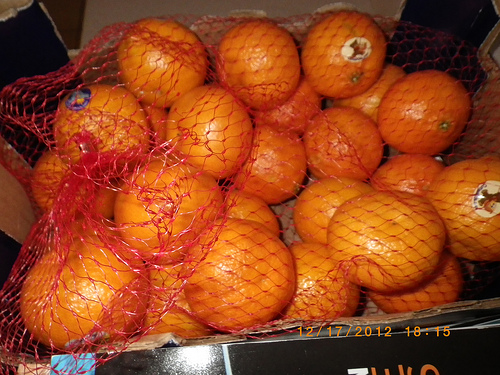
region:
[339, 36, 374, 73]
sticker on an orange fruit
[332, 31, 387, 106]
sticker on an orange fruit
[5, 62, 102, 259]
portion of red mesh bag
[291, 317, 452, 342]
date and time picture was taken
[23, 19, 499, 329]
large bag of oranges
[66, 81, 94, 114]
sticker on an orange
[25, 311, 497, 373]
black printed box oranges are in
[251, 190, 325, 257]
the bottom of the box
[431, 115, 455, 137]
the end of the orange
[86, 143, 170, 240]
a hole torn in the bag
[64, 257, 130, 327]
light reflects off orange rind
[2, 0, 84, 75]
torn edges of the box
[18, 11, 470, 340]
Red netting over oranges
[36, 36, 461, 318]
Pile of oranges in box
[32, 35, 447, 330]
The fruit is round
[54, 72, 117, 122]
Blue sticker on orange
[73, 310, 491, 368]
Side of box is black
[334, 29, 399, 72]
White and brown sticker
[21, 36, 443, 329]
Bag of oranges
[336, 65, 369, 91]
Orange has a green stem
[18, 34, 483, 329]
Oranges piled on top of each other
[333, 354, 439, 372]
Orange letters on side of box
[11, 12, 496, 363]
bags of oranges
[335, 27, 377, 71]
sticker on orange is white and brown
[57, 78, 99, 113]
sticker is blue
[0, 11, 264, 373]
bag of oranges is red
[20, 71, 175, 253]
bag with oranges is a net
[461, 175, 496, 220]
sticker over orange is yellow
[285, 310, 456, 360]
picture was taken on 2012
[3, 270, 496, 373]
oranges are on a black surface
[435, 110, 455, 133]
center of orange has a brown spot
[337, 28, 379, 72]
sticker has a brown design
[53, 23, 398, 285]
oranges in bag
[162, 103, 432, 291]
fruits are orange and round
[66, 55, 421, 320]
bag is red and mesh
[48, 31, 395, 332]
red bag in brown cardboard box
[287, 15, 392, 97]
oranges are small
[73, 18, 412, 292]
fruits are orange and yellow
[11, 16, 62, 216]
brown cardboard behind oranges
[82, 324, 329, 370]
black front on box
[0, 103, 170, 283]
red bag is tied shut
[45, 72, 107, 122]
oranges have blue stickers